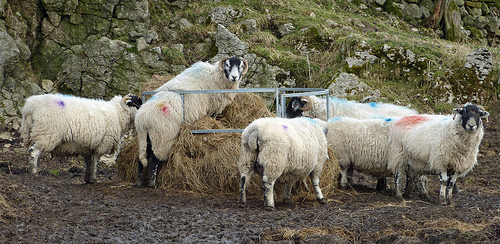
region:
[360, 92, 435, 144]
paint marking the backs of sheep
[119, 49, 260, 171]
sheep climbing in the hay feeder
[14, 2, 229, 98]
rocky hill behind the sheep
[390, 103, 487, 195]
sheep with red mark on back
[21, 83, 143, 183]
sheep with a purple mark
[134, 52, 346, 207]
sheep feeding from the hay rack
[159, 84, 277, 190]
hay in the sheep feeder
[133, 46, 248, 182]
sheep looking at the camera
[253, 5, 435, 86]
grass growing on the rocky hillside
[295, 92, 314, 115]
horn on the sheep head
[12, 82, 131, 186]
sheep in the field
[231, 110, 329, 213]
sheep in the field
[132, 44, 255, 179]
sheep in the field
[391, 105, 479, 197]
sheep in the field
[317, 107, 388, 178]
sheep in the field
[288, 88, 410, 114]
sheep in the field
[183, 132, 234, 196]
hay in the tray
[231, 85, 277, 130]
hay in the tray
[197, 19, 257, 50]
rock on the hillside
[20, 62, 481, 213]
sheep standing near hay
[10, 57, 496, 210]
sheep have various colored dots on them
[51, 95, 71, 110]
a blue dot on the sheep on far left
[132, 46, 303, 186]
a sheep on hay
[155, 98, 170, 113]
red dot on a sheep standing on hay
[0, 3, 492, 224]
the foothills of a mountain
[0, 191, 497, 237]
a muddy area in front of sheep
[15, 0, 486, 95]
rocks and stone at the bottom of mountain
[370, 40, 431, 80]
moss growing on the rocks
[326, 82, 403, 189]
two sheeps at right have turquoise dots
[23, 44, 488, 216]
group of adult sheep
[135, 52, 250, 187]
sheep standing on straw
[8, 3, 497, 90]
rocky and grassy slope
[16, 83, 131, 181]
sheep with purple dot on back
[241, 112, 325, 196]
sheep with purple dot on back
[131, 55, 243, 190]
sheep with red dot on back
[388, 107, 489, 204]
sheep with large red dot on back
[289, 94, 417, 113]
sheep with blue dot on back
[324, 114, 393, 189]
sheep with blue dot on back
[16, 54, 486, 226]
sheep standing on dark grey colored grounds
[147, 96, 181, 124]
the mark is red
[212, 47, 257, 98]
sheep's face is black and white